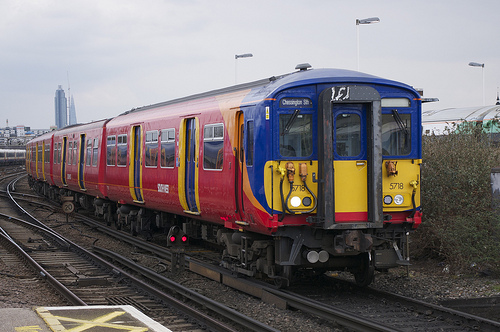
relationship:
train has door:
[25, 63, 422, 284] [180, 114, 200, 214]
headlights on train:
[291, 196, 302, 207] [25, 63, 422, 284]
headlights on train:
[394, 195, 405, 203] [25, 63, 422, 284]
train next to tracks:
[25, 63, 422, 284] [0, 170, 282, 331]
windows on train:
[202, 123, 225, 171] [25, 63, 422, 284]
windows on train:
[276, 111, 314, 162] [25, 63, 422, 284]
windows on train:
[382, 112, 414, 157] [25, 63, 422, 284]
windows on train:
[160, 127, 174, 168] [25, 63, 422, 284]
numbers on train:
[390, 182, 401, 189] [25, 63, 422, 284]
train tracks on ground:
[1, 171, 499, 331] [4, 164, 499, 331]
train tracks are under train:
[44, 165, 374, 291] [25, 63, 422, 284]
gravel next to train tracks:
[406, 269, 498, 299] [278, 285, 498, 329]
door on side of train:
[131, 122, 144, 201] [25, 63, 422, 284]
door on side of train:
[79, 132, 86, 191] [25, 63, 422, 284]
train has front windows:
[25, 63, 422, 284] [275, 111, 413, 164]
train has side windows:
[25, 63, 422, 284] [144, 122, 225, 169]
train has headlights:
[25, 63, 422, 284] [292, 194, 402, 206]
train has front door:
[25, 63, 422, 284] [235, 110, 246, 224]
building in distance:
[55, 84, 67, 128] [40, 78, 95, 127]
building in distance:
[70, 96, 78, 124] [40, 78, 95, 127]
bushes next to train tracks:
[422, 116, 497, 274] [1, 171, 499, 331]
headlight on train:
[291, 197, 301, 205] [25, 63, 422, 284]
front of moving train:
[261, 62, 424, 282] [25, 63, 422, 284]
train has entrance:
[25, 63, 422, 284] [331, 110, 369, 224]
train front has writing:
[261, 62, 424, 282] [280, 98, 310, 106]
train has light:
[25, 63, 422, 284] [291, 196, 302, 207]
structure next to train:
[425, 105, 497, 135] [25, 63, 422, 284]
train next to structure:
[25, 63, 422, 284] [491, 173, 499, 192]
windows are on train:
[382, 112, 414, 157] [25, 63, 422, 284]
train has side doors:
[25, 63, 422, 284] [127, 115, 200, 214]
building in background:
[55, 84, 67, 128] [4, 2, 114, 131]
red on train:
[203, 173, 231, 212] [25, 63, 422, 284]